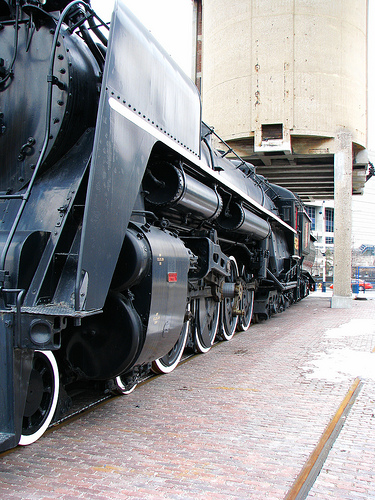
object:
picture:
[0, 0, 374, 499]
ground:
[0, 296, 374, 499]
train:
[0, 1, 316, 452]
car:
[330, 276, 373, 291]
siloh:
[191, 1, 374, 309]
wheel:
[18, 348, 61, 446]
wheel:
[191, 268, 220, 354]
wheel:
[239, 264, 255, 331]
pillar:
[332, 141, 352, 307]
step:
[0, 432, 21, 453]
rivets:
[57, 53, 65, 61]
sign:
[302, 221, 310, 253]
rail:
[49, 339, 221, 427]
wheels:
[152, 302, 191, 374]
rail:
[200, 119, 281, 201]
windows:
[324, 206, 333, 231]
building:
[302, 201, 335, 277]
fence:
[351, 264, 374, 283]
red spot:
[167, 270, 177, 283]